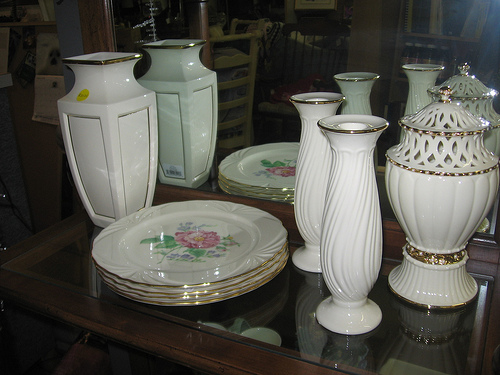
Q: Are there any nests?
A: No, there are no nests.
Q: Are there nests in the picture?
A: No, there are no nests.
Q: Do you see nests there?
A: No, there are no nests.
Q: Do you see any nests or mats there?
A: No, there are no nests or mats.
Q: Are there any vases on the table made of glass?
A: Yes, there is a vase on the table.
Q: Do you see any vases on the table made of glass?
A: Yes, there is a vase on the table.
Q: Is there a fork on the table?
A: No, there is a vase on the table.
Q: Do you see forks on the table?
A: No, there is a vase on the table.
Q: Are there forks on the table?
A: No, there is a vase on the table.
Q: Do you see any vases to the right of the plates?
A: Yes, there is a vase to the right of the plates.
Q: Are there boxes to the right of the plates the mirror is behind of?
A: No, there is a vase to the right of the plates.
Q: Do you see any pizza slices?
A: No, there are no pizza slices.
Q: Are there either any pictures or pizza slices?
A: No, there are no pizza slices or pictures.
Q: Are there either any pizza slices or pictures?
A: No, there are no pizza slices or pictures.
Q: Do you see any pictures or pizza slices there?
A: No, there are no pizza slices or pictures.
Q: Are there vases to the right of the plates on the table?
A: Yes, there is a vase to the right of the plates.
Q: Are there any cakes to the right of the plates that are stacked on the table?
A: No, there is a vase to the right of the plates.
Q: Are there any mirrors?
A: Yes, there is a mirror.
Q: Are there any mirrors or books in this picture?
A: Yes, there is a mirror.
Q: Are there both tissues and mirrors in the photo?
A: No, there is a mirror but no tissues.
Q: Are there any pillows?
A: No, there are no pillows.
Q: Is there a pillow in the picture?
A: No, there are no pillows.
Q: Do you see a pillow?
A: No, there are no pillows.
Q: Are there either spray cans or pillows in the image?
A: No, there are no pillows or spray cans.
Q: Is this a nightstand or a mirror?
A: This is a mirror.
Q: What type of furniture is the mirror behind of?
A: The mirror is behind the table.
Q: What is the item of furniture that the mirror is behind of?
A: The piece of furniture is a table.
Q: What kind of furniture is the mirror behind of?
A: The mirror is behind the table.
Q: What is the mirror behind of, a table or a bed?
A: The mirror is behind a table.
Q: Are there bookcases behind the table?
A: No, there is a mirror behind the table.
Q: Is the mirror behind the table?
A: Yes, the mirror is behind the table.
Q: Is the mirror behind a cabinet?
A: No, the mirror is behind the table.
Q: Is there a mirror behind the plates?
A: Yes, there is a mirror behind the plates.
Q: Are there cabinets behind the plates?
A: No, there is a mirror behind the plates.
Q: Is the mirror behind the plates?
A: Yes, the mirror is behind the plates.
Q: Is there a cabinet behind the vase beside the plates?
A: No, there is a mirror behind the vase.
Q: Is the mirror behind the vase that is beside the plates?
A: Yes, the mirror is behind the vase.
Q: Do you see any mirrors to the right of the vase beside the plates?
A: Yes, there is a mirror to the right of the vase.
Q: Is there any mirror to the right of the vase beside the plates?
A: Yes, there is a mirror to the right of the vase.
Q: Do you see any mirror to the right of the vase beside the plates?
A: Yes, there is a mirror to the right of the vase.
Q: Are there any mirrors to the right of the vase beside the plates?
A: Yes, there is a mirror to the right of the vase.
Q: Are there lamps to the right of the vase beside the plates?
A: No, there is a mirror to the right of the vase.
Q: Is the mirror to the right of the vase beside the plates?
A: Yes, the mirror is to the right of the vase.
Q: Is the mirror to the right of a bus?
A: No, the mirror is to the right of the vase.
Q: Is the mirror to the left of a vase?
A: No, the mirror is to the right of a vase.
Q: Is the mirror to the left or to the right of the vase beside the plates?
A: The mirror is to the right of the vase.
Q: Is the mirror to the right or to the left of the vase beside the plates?
A: The mirror is to the right of the vase.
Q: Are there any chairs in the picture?
A: Yes, there is a chair.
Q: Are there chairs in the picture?
A: Yes, there is a chair.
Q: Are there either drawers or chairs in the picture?
A: Yes, there is a chair.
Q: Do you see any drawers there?
A: No, there are no drawers.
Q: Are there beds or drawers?
A: No, there are no drawers or beds.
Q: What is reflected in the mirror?
A: The chair is reflected in the mirror.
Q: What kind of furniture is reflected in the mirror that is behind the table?
A: The piece of furniture is a chair.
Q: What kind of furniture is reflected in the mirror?
A: The piece of furniture is a chair.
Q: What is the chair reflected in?
A: The chair is reflected in the mirror.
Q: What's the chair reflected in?
A: The chair is reflected in the mirror.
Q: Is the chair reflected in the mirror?
A: Yes, the chair is reflected in the mirror.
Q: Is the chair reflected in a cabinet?
A: No, the chair is reflected in the mirror.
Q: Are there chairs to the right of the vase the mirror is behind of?
A: Yes, there is a chair to the right of the vase.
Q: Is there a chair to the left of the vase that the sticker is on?
A: No, the chair is to the right of the vase.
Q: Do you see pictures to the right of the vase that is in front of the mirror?
A: No, there is a chair to the right of the vase.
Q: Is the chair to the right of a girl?
A: No, the chair is to the right of a vase.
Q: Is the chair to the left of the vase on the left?
A: No, the chair is to the right of the vase.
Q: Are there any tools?
A: No, there are no tools.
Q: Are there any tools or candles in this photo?
A: No, there are no tools or candles.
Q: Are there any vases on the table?
A: Yes, there is a vase on the table.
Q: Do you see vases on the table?
A: Yes, there is a vase on the table.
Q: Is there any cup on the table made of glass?
A: No, there is a vase on the table.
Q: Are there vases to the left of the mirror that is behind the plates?
A: Yes, there is a vase to the left of the mirror.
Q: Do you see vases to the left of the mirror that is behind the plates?
A: Yes, there is a vase to the left of the mirror.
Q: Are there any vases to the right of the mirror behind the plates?
A: No, the vase is to the left of the mirror.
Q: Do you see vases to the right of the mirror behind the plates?
A: No, the vase is to the left of the mirror.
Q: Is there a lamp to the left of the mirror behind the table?
A: No, there is a vase to the left of the mirror.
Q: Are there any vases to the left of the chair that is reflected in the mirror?
A: Yes, there is a vase to the left of the chair.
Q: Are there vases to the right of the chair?
A: No, the vase is to the left of the chair.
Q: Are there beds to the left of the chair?
A: No, there is a vase to the left of the chair.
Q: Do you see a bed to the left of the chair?
A: No, there is a vase to the left of the chair.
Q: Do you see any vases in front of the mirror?
A: Yes, there is a vase in front of the mirror.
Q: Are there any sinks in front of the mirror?
A: No, there is a vase in front of the mirror.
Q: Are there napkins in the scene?
A: No, there are no napkins.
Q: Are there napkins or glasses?
A: No, there are no napkins or glasses.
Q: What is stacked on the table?
A: The plates are stacked on the table.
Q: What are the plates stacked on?
A: The plates are stacked on the table.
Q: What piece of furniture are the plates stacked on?
A: The plates are stacked on the table.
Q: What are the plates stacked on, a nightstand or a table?
A: The plates are stacked on a table.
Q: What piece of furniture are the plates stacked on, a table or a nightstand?
A: The plates are stacked on a table.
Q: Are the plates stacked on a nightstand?
A: No, the plates are stacked on a table.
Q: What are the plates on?
A: The plates are on the table.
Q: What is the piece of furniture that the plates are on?
A: The piece of furniture is a table.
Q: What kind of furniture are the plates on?
A: The plates are on the table.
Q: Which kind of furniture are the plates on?
A: The plates are on the table.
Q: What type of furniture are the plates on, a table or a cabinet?
A: The plates are on a table.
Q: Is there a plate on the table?
A: Yes, there are plates on the table.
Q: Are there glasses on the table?
A: No, there are plates on the table.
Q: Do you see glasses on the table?
A: No, there are plates on the table.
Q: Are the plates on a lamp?
A: No, the plates are on the table.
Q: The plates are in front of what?
A: The plates are in front of the mirror.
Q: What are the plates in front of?
A: The plates are in front of the mirror.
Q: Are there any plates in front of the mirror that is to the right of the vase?
A: Yes, there are plates in front of the mirror.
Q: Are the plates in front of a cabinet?
A: No, the plates are in front of the mirror.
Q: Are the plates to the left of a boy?
A: No, the plates are to the left of a vase.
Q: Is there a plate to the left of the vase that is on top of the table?
A: Yes, there are plates to the left of the vase.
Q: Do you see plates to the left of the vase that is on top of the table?
A: Yes, there are plates to the left of the vase.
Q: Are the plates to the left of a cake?
A: No, the plates are to the left of a vase.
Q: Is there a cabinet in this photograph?
A: No, there are no cabinets.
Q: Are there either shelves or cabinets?
A: No, there are no cabinets or shelves.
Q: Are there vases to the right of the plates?
A: Yes, there is a vase to the right of the plates.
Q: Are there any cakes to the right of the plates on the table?
A: No, there is a vase to the right of the plates.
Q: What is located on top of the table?
A: The vase is on top of the table.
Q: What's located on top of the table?
A: The vase is on top of the table.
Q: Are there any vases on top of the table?
A: Yes, there is a vase on top of the table.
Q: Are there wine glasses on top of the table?
A: No, there is a vase on top of the table.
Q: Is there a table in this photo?
A: Yes, there is a table.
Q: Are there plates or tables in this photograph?
A: Yes, there is a table.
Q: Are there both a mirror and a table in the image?
A: Yes, there are both a table and a mirror.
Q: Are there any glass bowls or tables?
A: Yes, there is a glass table.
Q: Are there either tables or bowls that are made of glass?
A: Yes, the table is made of glass.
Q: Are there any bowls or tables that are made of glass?
A: Yes, the table is made of glass.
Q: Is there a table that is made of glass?
A: Yes, there is a table that is made of glass.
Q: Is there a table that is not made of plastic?
A: Yes, there is a table that is made of glass.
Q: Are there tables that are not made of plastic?
A: Yes, there is a table that is made of glass.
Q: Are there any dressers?
A: No, there are no dressers.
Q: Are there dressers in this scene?
A: No, there are no dressers.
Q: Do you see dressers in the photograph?
A: No, there are no dressers.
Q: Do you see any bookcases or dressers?
A: No, there are no dressers or bookcases.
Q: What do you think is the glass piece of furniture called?
A: The piece of furniture is a table.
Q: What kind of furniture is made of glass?
A: The furniture is a table.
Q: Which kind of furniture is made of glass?
A: The furniture is a table.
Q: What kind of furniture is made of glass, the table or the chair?
A: The table is made of glass.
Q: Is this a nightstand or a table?
A: This is a table.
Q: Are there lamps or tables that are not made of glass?
A: No, there is a table but it is made of glass.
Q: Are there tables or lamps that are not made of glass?
A: No, there is a table but it is made of glass.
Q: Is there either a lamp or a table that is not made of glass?
A: No, there is a table but it is made of glass.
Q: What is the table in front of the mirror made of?
A: The table is made of glass.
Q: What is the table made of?
A: The table is made of glass.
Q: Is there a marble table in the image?
A: No, there is a table but it is made of glass.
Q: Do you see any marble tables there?
A: No, there is a table but it is made of glass.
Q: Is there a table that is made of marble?
A: No, there is a table but it is made of glass.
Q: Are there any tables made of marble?
A: No, there is a table but it is made of glass.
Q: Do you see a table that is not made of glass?
A: No, there is a table but it is made of glass.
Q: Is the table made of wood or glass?
A: The table is made of glass.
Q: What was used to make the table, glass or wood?
A: The table is made of glass.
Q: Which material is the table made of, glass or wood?
A: The table is made of glass.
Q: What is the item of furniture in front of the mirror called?
A: The piece of furniture is a table.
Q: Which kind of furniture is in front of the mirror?
A: The piece of furniture is a table.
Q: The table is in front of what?
A: The table is in front of the mirror.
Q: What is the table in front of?
A: The table is in front of the mirror.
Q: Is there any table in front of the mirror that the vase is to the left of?
A: Yes, there is a table in front of the mirror.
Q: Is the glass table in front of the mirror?
A: Yes, the table is in front of the mirror.